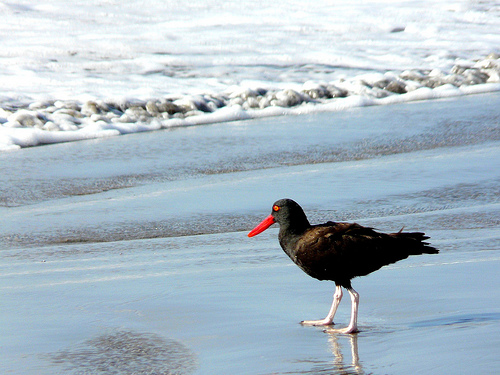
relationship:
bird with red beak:
[249, 198, 439, 335] [248, 212, 274, 236]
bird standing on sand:
[248, 198, 439, 335] [231, 287, 306, 349]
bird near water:
[249, 198, 439, 335] [1, 0, 499, 152]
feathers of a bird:
[302, 200, 432, 289] [257, 183, 401, 326]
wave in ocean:
[4, 3, 496, 155] [0, 0, 500, 91]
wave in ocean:
[151, 52, 416, 97] [2, 0, 498, 172]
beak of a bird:
[247, 206, 279, 261] [257, 183, 401, 326]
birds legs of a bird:
[323, 285, 360, 334] [266, 182, 399, 342]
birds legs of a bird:
[323, 285, 360, 334] [234, 189, 451, 353]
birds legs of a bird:
[300, 280, 343, 326] [234, 189, 451, 353]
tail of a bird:
[398, 225, 443, 262] [260, 175, 413, 335]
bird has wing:
[249, 198, 439, 335] [296, 220, 439, 281]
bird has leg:
[248, 198, 439, 335] [295, 287, 367, 342]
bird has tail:
[248, 198, 439, 335] [383, 223, 441, 264]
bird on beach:
[248, 198, 439, 335] [0, 90, 499, 374]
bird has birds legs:
[249, 198, 439, 335] [300, 280, 343, 326]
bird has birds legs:
[249, 198, 439, 335] [323, 285, 360, 334]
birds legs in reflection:
[300, 280, 343, 326] [303, 329, 380, 373]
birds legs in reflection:
[323, 285, 360, 334] [303, 329, 380, 373]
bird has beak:
[249, 198, 439, 335] [249, 218, 271, 237]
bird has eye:
[249, 198, 439, 335] [271, 203, 282, 213]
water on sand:
[1, 0, 499, 152] [2, 91, 498, 373]